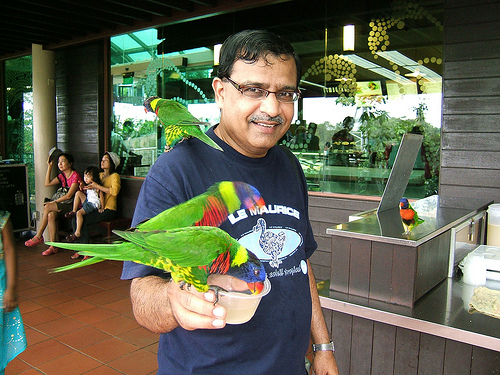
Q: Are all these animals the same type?
A: Yes, all the animals are birds.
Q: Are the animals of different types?
A: No, all the animals are birds.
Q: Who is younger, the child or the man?
A: The child is younger than the man.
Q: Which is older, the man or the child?
A: The man is older than the child.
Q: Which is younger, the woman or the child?
A: The child is younger than the woman.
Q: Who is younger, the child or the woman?
A: The child is younger than the woman.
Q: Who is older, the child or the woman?
A: The woman is older than the child.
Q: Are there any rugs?
A: No, there are no rugs.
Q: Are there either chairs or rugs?
A: No, there are no rugs or chairs.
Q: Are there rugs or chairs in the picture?
A: No, there are no rugs or chairs.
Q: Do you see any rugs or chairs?
A: No, there are no rugs or chairs.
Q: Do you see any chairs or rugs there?
A: No, there are no rugs or chairs.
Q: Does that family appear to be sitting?
A: Yes, the family is sitting.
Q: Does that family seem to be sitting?
A: Yes, the family is sitting.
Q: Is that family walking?
A: No, the family is sitting.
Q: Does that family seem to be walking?
A: No, the family is sitting.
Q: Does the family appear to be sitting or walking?
A: The family is sitting.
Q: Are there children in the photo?
A: Yes, there is a child.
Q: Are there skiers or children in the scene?
A: Yes, there is a child.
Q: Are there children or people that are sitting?
A: Yes, the child is sitting.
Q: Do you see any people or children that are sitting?
A: Yes, the child is sitting.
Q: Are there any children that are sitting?
A: Yes, there is a child that is sitting.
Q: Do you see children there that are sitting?
A: Yes, there is a child that is sitting.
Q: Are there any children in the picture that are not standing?
A: Yes, there is a child that is sitting.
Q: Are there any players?
A: No, there are no players.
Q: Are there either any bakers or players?
A: No, there are no players or bakers.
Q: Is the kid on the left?
A: Yes, the kid is on the left of the image.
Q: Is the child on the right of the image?
A: No, the child is on the left of the image.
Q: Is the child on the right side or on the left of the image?
A: The child is on the left of the image.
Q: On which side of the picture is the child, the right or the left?
A: The child is on the left of the image.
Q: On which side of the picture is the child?
A: The child is on the left of the image.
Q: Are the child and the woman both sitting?
A: Yes, both the child and the woman are sitting.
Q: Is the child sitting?
A: Yes, the child is sitting.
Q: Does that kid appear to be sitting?
A: Yes, the kid is sitting.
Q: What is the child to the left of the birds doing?
A: The child is sitting.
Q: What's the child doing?
A: The child is sitting.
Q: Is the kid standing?
A: No, the kid is sitting.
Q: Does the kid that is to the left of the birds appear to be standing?
A: No, the kid is sitting.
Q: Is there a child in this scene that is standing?
A: No, there is a child but he is sitting.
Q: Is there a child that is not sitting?
A: No, there is a child but he is sitting.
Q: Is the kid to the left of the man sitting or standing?
A: The kid is sitting.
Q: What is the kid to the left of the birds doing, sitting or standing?
A: The kid is sitting.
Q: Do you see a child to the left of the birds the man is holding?
A: Yes, there is a child to the left of the birds.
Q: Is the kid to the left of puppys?
A: No, the kid is to the left of the birds.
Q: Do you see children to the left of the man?
A: Yes, there is a child to the left of the man.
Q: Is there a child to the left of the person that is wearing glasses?
A: Yes, there is a child to the left of the man.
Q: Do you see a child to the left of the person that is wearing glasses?
A: Yes, there is a child to the left of the man.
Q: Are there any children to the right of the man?
A: No, the child is to the left of the man.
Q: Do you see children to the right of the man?
A: No, the child is to the left of the man.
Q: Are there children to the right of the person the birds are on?
A: No, the child is to the left of the man.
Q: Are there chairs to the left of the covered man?
A: No, there is a child to the left of the man.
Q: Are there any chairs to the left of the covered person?
A: No, there is a child to the left of the man.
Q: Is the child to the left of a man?
A: Yes, the child is to the left of a man.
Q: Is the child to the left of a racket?
A: No, the child is to the left of a man.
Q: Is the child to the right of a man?
A: No, the child is to the left of a man.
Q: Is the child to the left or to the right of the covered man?
A: The child is to the left of the man.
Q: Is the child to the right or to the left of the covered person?
A: The child is to the left of the man.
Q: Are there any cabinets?
A: No, there are no cabinets.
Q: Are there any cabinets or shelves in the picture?
A: No, there are no cabinets or shelves.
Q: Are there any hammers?
A: No, there are no hammers.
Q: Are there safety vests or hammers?
A: No, there are no hammers or safety vests.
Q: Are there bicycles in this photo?
A: No, there are no bicycles.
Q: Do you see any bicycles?
A: No, there are no bicycles.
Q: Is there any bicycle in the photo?
A: No, there are no bicycles.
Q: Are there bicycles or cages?
A: No, there are no bicycles or cages.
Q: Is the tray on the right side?
A: Yes, the tray is on the right of the image.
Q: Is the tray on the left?
A: No, the tray is on the right of the image.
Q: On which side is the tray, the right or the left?
A: The tray is on the right of the image.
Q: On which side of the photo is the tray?
A: The tray is on the right of the image.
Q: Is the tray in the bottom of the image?
A: Yes, the tray is in the bottom of the image.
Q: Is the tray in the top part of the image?
A: No, the tray is in the bottom of the image.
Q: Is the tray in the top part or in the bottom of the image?
A: The tray is in the bottom of the image.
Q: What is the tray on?
A: The tray is on the counter.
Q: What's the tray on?
A: The tray is on the counter.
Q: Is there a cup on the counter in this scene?
A: No, there is a tray on the counter.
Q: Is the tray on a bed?
A: No, the tray is on the counter.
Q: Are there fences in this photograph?
A: No, there are no fences.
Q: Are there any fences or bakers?
A: No, there are no fences or bakers.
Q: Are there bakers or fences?
A: No, there are no fences or bakers.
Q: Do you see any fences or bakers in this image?
A: No, there are no fences or bakers.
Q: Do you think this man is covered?
A: Yes, the man is covered.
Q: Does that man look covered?
A: Yes, the man is covered.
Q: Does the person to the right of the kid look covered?
A: Yes, the man is covered.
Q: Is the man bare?
A: No, the man is covered.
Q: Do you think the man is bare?
A: No, the man is covered.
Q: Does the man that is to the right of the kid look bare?
A: No, the man is covered.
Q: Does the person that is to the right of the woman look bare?
A: No, the man is covered.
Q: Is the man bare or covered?
A: The man is covered.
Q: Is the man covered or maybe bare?
A: The man is covered.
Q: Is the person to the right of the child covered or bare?
A: The man is covered.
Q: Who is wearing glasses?
A: The man is wearing glasses.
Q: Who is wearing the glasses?
A: The man is wearing glasses.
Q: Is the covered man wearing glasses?
A: Yes, the man is wearing glasses.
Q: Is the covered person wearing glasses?
A: Yes, the man is wearing glasses.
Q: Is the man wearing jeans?
A: No, the man is wearing glasses.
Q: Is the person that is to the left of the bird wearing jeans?
A: No, the man is wearing glasses.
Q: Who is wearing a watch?
A: The man is wearing a watch.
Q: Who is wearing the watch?
A: The man is wearing a watch.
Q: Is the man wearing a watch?
A: Yes, the man is wearing a watch.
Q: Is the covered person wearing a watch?
A: Yes, the man is wearing a watch.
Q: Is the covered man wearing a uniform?
A: No, the man is wearing a watch.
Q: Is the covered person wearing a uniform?
A: No, the man is wearing a watch.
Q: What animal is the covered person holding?
A: The man is holding the birds.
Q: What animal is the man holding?
A: The man is holding the birds.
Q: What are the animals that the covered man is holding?
A: The animals are birds.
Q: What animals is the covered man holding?
A: The man is holding the birds.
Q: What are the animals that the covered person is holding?
A: The animals are birds.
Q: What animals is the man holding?
A: The man is holding the birds.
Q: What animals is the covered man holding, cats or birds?
A: The man is holding birds.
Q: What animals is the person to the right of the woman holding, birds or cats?
A: The man is holding birds.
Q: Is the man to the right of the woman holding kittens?
A: No, the man is holding the birds.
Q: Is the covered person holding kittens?
A: No, the man is holding the birds.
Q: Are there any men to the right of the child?
A: Yes, there is a man to the right of the child.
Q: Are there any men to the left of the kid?
A: No, the man is to the right of the kid.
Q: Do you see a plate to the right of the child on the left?
A: No, there is a man to the right of the child.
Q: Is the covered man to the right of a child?
A: Yes, the man is to the right of a child.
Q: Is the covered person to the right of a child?
A: Yes, the man is to the right of a child.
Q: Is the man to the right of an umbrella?
A: No, the man is to the right of a child.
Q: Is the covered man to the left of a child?
A: No, the man is to the right of a child.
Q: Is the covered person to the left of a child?
A: No, the man is to the right of a child.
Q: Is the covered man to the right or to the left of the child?
A: The man is to the right of the child.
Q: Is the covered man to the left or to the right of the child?
A: The man is to the right of the child.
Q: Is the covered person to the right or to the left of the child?
A: The man is to the right of the child.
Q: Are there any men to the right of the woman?
A: Yes, there is a man to the right of the woman.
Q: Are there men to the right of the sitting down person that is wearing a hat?
A: Yes, there is a man to the right of the woman.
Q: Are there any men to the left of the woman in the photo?
A: No, the man is to the right of the woman.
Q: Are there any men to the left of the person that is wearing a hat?
A: No, the man is to the right of the woman.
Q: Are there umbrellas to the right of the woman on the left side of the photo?
A: No, there is a man to the right of the woman.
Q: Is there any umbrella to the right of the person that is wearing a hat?
A: No, there is a man to the right of the woman.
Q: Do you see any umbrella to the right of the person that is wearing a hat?
A: No, there is a man to the right of the woman.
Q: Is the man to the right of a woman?
A: Yes, the man is to the right of a woman.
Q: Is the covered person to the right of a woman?
A: Yes, the man is to the right of a woman.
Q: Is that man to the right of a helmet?
A: No, the man is to the right of a woman.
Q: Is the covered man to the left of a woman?
A: No, the man is to the right of a woman.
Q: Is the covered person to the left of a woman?
A: No, the man is to the right of a woman.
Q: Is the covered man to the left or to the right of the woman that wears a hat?
A: The man is to the right of the woman.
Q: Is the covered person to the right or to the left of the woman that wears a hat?
A: The man is to the right of the woman.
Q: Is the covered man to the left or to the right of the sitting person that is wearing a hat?
A: The man is to the right of the woman.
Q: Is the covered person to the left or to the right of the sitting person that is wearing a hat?
A: The man is to the right of the woman.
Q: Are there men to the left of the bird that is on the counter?
A: Yes, there is a man to the left of the bird.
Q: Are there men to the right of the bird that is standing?
A: No, the man is to the left of the bird.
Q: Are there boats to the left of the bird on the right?
A: No, there is a man to the left of the bird.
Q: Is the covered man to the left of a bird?
A: Yes, the man is to the left of a bird.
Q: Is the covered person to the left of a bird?
A: Yes, the man is to the left of a bird.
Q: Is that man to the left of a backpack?
A: No, the man is to the left of a bird.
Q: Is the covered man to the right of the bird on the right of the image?
A: No, the man is to the left of the bird.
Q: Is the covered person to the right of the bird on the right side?
A: No, the man is to the left of the bird.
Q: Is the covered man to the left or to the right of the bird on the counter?
A: The man is to the left of the bird.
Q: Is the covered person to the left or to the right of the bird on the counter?
A: The man is to the left of the bird.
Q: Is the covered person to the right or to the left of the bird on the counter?
A: The man is to the left of the bird.